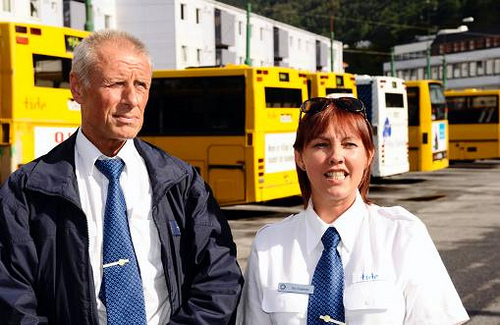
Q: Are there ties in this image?
A: Yes, there is a tie.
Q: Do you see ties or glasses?
A: Yes, there is a tie.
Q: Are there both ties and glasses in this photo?
A: Yes, there are both a tie and glasses.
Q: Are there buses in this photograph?
A: Yes, there are buses.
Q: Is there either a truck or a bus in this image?
A: Yes, there are buses.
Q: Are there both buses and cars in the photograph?
A: No, there are buses but no cars.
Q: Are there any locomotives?
A: No, there are no locomotives.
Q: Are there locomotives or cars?
A: No, there are no locomotives or cars.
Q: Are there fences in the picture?
A: No, there are no fences.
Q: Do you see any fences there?
A: No, there are no fences.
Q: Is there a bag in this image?
A: No, there are no bags.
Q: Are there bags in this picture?
A: No, there are no bags.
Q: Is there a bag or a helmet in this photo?
A: No, there are no bags or helmets.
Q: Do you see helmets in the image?
A: No, there are no helmets.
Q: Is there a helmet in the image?
A: No, there are no helmets.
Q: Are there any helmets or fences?
A: No, there are no helmets or fences.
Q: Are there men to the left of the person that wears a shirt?
A: Yes, there is a man to the left of the person.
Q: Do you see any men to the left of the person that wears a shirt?
A: Yes, there is a man to the left of the person.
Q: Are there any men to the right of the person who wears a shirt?
A: No, the man is to the left of the person.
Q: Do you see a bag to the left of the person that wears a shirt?
A: No, there is a man to the left of the person.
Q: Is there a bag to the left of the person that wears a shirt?
A: No, there is a man to the left of the person.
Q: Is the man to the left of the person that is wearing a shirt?
A: Yes, the man is to the left of the person.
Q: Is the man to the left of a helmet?
A: No, the man is to the left of the person.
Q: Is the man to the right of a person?
A: No, the man is to the left of a person.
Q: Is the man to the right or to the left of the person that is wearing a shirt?
A: The man is to the left of the person.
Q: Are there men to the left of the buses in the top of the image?
A: Yes, there is a man to the left of the buses.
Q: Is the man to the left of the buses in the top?
A: Yes, the man is to the left of the buses.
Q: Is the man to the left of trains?
A: No, the man is to the left of the buses.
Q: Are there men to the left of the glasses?
A: Yes, there is a man to the left of the glasses.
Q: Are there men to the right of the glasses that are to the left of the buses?
A: No, the man is to the left of the glasses.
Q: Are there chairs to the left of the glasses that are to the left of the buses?
A: No, there is a man to the left of the glasses.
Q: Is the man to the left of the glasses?
A: Yes, the man is to the left of the glasses.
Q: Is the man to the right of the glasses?
A: No, the man is to the left of the glasses.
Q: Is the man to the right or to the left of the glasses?
A: The man is to the left of the glasses.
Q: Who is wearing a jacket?
A: The man is wearing a jacket.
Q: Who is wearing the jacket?
A: The man is wearing a jacket.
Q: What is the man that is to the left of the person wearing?
A: The man is wearing a jacket.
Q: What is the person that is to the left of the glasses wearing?
A: The man is wearing a jacket.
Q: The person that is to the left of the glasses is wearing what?
A: The man is wearing a jacket.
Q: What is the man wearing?
A: The man is wearing a jacket.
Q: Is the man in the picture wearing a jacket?
A: Yes, the man is wearing a jacket.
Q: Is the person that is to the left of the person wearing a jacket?
A: Yes, the man is wearing a jacket.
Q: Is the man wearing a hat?
A: No, the man is wearing a jacket.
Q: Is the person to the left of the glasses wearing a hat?
A: No, the man is wearing a jacket.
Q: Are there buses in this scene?
A: Yes, there are buses.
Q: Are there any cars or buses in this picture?
A: Yes, there are buses.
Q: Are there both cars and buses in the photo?
A: No, there are buses but no cars.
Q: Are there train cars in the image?
A: No, there are no train cars.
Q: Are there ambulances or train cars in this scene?
A: No, there are no train cars or ambulances.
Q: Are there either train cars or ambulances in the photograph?
A: No, there are no train cars or ambulances.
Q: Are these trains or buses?
A: These are buses.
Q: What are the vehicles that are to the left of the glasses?
A: The vehicles are buses.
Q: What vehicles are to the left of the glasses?
A: The vehicles are buses.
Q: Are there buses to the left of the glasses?
A: Yes, there are buses to the left of the glasses.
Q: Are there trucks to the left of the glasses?
A: No, there are buses to the left of the glasses.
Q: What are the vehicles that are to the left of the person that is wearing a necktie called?
A: The vehicles are buses.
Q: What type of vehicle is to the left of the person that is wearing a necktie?
A: The vehicles are buses.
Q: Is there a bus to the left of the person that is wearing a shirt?
A: Yes, there are buses to the left of the person.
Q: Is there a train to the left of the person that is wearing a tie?
A: No, there are buses to the left of the person.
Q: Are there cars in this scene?
A: No, there are no cars.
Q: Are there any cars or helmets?
A: No, there are no cars or helmets.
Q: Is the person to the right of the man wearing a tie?
A: Yes, the person is wearing a tie.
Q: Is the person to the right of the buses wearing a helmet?
A: No, the person is wearing a tie.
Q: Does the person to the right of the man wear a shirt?
A: Yes, the person wears a shirt.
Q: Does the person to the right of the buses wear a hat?
A: No, the person wears a shirt.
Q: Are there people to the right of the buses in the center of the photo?
A: Yes, there is a person to the right of the buses.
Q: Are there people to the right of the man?
A: Yes, there is a person to the right of the man.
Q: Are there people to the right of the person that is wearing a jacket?
A: Yes, there is a person to the right of the man.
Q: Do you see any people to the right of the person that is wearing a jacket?
A: Yes, there is a person to the right of the man.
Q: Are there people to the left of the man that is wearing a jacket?
A: No, the person is to the right of the man.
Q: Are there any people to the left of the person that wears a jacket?
A: No, the person is to the right of the man.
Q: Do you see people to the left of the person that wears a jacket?
A: No, the person is to the right of the man.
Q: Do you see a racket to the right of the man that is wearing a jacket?
A: No, there is a person to the right of the man.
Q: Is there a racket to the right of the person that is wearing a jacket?
A: No, there is a person to the right of the man.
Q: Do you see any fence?
A: No, there are no fences.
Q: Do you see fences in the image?
A: No, there are no fences.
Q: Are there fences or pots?
A: No, there are no fences or pots.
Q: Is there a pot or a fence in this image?
A: No, there are no fences or pots.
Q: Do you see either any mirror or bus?
A: Yes, there are buses.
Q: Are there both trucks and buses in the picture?
A: No, there are buses but no trucks.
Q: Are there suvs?
A: No, there are no suvs.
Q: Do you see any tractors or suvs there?
A: No, there are no suvs or tractors.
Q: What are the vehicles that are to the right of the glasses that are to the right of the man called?
A: The vehicles are buses.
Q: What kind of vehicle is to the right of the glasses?
A: The vehicles are buses.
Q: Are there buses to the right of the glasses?
A: Yes, there are buses to the right of the glasses.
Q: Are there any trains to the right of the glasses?
A: No, there are buses to the right of the glasses.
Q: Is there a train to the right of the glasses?
A: No, there are buses to the right of the glasses.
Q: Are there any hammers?
A: No, there are no hammers.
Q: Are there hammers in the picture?
A: No, there are no hammers.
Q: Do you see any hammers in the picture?
A: No, there are no hammers.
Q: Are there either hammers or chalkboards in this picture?
A: No, there are no hammers or chalkboards.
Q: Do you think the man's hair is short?
A: Yes, the hair is short.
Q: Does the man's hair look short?
A: Yes, the hair is short.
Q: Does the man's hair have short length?
A: Yes, the hair is short.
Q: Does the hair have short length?
A: Yes, the hair is short.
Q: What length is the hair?
A: The hair is short.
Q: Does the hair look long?
A: No, the hair is short.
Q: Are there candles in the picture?
A: No, there are no candles.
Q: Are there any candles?
A: No, there are no candles.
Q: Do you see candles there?
A: No, there are no candles.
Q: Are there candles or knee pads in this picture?
A: No, there are no candles or knee pads.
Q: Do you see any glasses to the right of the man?
A: Yes, there are glasses to the right of the man.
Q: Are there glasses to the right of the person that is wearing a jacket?
A: Yes, there are glasses to the right of the man.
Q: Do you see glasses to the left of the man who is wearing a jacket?
A: No, the glasses are to the right of the man.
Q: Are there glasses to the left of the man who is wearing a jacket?
A: No, the glasses are to the right of the man.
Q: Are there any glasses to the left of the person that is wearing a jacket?
A: No, the glasses are to the right of the man.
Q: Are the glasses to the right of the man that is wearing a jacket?
A: Yes, the glasses are to the right of the man.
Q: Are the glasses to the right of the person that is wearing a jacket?
A: Yes, the glasses are to the right of the man.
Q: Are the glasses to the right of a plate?
A: No, the glasses are to the right of the man.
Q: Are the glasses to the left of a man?
A: No, the glasses are to the right of a man.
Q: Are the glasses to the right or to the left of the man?
A: The glasses are to the right of the man.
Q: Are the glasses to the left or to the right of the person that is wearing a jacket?
A: The glasses are to the right of the man.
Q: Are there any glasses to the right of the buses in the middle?
A: Yes, there are glasses to the right of the buses.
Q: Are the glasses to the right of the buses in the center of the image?
A: Yes, the glasses are to the right of the buses.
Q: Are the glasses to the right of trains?
A: No, the glasses are to the right of the buses.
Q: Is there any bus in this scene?
A: Yes, there are buses.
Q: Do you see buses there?
A: Yes, there are buses.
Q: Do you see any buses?
A: Yes, there are buses.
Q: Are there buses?
A: Yes, there are buses.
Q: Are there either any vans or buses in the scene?
A: Yes, there are buses.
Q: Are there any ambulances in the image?
A: No, there are no ambulances.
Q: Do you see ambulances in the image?
A: No, there are no ambulances.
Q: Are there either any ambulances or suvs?
A: No, there are no ambulances or suvs.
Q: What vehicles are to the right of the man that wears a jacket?
A: The vehicles are buses.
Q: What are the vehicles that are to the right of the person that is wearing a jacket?
A: The vehicles are buses.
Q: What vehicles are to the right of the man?
A: The vehicles are buses.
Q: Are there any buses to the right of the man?
A: Yes, there are buses to the right of the man.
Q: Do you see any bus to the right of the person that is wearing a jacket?
A: Yes, there are buses to the right of the man.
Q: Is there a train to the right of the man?
A: No, there are buses to the right of the man.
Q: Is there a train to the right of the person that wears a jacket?
A: No, there are buses to the right of the man.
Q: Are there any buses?
A: Yes, there are buses.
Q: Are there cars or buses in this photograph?
A: Yes, there are buses.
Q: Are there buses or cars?
A: Yes, there are buses.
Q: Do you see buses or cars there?
A: Yes, there are buses.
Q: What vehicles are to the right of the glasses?
A: The vehicles are buses.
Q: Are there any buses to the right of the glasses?
A: Yes, there are buses to the right of the glasses.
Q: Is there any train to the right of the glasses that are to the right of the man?
A: No, there are buses to the right of the glasses.